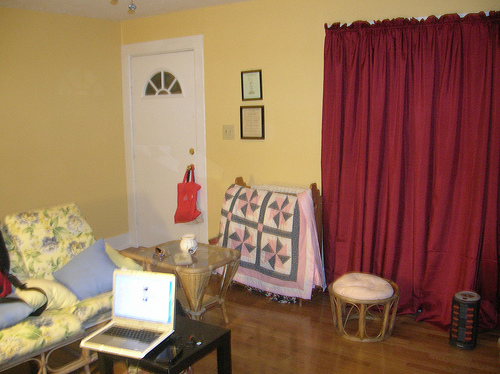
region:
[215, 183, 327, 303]
Pink, white and grey quilt on a rack.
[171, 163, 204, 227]
Red bag hanging on doorknob.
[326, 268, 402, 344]
Stool with white cushion.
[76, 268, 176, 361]
Laptop computer on table.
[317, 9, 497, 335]
Red curtains covering the window.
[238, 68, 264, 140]
Two picture frames on the wall.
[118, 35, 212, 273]
White entrance door.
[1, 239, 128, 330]
Purple and yellow pillows on the couch.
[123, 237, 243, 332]
Wooden table with a glass top.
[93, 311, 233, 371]
Square black table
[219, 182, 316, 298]
Grey pink and white quilt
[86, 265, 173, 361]
An open laptop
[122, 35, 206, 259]
A white door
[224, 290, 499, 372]
Shiny hardwood flooring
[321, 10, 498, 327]
Maroon colored panel drapes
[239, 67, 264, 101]
Wall picture with a black frame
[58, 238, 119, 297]
A periwinkle blue pillow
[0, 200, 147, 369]
A yellow floral couch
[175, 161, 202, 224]
Red tote bag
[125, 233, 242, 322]
A glass top wicker end table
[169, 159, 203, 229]
red bag on the door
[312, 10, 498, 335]
red curtains covering the window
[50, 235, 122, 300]
blue pillow on the couch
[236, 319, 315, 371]
shinny wood floors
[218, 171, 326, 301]
pink and blue pinwheel quilt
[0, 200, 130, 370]
floral couch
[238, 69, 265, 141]
two pictures on the wall by the door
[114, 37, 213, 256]
white door with a window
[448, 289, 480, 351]
black cylindrical object on the floor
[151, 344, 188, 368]
black cell phone on the table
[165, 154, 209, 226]
a red bag on the door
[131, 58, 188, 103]
the window on the door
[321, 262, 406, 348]
a wooden foot stool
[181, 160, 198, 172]
the knob on the door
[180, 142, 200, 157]
the lock on the door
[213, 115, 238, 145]
the light switch by the door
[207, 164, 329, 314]
a pink and grey blanket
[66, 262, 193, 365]
a laptop on a table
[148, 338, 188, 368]
a cell phone on a table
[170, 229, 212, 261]
a white vase on the table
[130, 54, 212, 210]
this s the door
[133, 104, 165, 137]
the door is white in color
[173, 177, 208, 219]
this is a bag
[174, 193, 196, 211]
the bag is red in color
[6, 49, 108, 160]
this is the wall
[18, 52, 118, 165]
the wall is cream in color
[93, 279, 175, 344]
this is a laptop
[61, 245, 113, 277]
this is a pillow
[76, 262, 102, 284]
the pillow is blue in color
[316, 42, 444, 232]
this is a curtain